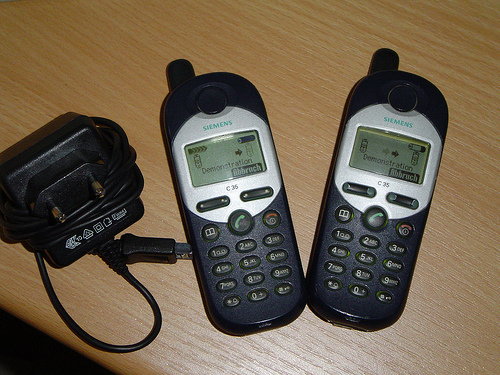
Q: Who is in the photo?
A: No one.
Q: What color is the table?
A: Brown.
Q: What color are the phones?
A: Black.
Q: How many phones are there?
A: Two.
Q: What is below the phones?
A: A table.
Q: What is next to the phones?
A: A charger.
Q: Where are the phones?
A: On the table.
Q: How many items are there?
A: Three.